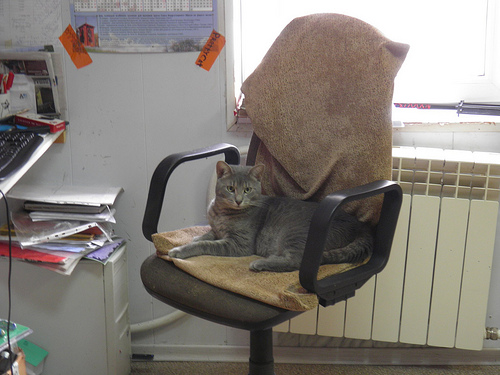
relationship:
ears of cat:
[213, 157, 268, 181] [161, 159, 412, 280]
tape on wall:
[58, 23, 93, 69] [2, 1, 250, 350]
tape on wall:
[196, 27, 226, 71] [2, 1, 250, 350]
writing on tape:
[190, 28, 222, 64] [190, 28, 225, 69]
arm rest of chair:
[140, 140, 242, 242] [142, 13, 407, 367]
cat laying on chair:
[169, 162, 372, 267] [142, 13, 407, 367]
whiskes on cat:
[246, 192, 264, 208] [213, 163, 308, 263]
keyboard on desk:
[2, 126, 46, 191] [0, 83, 72, 241]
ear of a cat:
[208, 157, 233, 177] [167, 151, 374, 286]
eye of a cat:
[240, 185, 258, 201] [169, 162, 372, 267]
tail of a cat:
[283, 232, 379, 262] [186, 150, 411, 337]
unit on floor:
[13, 229, 138, 371] [110, 330, 498, 373]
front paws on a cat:
[167, 233, 219, 258] [171, 158, 381, 278]